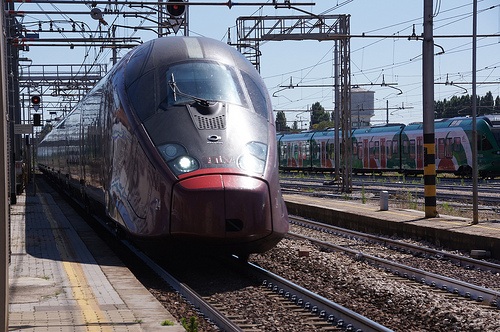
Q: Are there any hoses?
A: No, there are no hoses.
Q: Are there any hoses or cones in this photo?
A: No, there are no hoses or cones.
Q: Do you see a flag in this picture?
A: No, there are no flags.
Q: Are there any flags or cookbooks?
A: No, there are no flags or cookbooks.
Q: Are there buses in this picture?
A: No, there are no buses.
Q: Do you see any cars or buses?
A: No, there are no buses or cars.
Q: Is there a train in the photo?
A: Yes, there is a train.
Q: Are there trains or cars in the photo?
A: Yes, there is a train.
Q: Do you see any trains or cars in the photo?
A: Yes, there is a train.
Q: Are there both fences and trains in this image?
A: No, there is a train but no fences.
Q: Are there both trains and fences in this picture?
A: No, there is a train but no fences.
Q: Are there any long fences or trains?
A: Yes, there is a long train.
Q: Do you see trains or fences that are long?
A: Yes, the train is long.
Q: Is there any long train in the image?
A: Yes, there is a long train.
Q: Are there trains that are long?
A: Yes, there is a train that is long.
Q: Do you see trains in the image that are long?
A: Yes, there is a train that is long.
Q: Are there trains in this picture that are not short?
A: Yes, there is a long train.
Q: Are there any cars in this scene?
A: No, there are no cars.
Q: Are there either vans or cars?
A: No, there are no cars or vans.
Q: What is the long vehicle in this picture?
A: The vehicle is a train.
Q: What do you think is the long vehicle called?
A: The vehicle is a train.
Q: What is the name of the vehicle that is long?
A: The vehicle is a train.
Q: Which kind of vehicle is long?
A: The vehicle is a train.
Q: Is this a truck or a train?
A: This is a train.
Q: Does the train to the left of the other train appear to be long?
A: Yes, the train is long.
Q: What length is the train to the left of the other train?
A: The train is long.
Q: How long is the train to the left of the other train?
A: The train is long.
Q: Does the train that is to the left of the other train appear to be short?
A: No, the train is long.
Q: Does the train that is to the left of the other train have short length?
A: No, the train is long.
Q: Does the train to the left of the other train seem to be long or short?
A: The train is long.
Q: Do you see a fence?
A: No, there are no fences.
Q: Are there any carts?
A: No, there are no carts.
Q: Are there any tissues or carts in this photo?
A: No, there are no carts or tissues.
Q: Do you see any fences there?
A: No, there are no fences.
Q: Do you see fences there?
A: No, there are no fences.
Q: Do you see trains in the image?
A: Yes, there is a train.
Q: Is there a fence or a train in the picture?
A: Yes, there is a train.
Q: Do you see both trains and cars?
A: No, there is a train but no cars.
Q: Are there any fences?
A: No, there are no fences.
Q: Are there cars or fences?
A: No, there are no fences or cars.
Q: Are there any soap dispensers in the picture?
A: No, there are no soap dispensers.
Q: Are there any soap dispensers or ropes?
A: No, there are no soap dispensers or ropes.